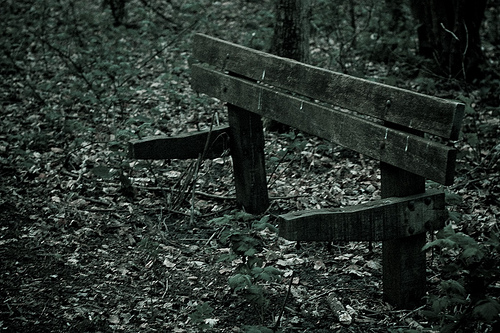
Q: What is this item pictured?
A: A broken bench.